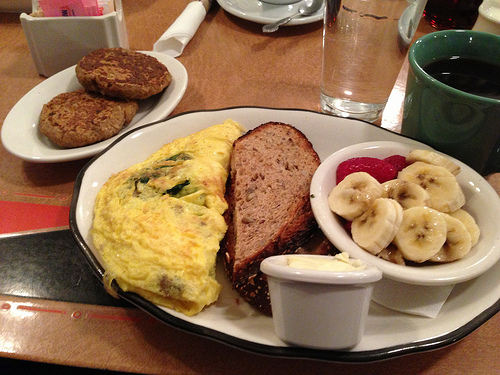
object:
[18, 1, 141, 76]
container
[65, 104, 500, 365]
plate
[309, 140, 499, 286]
bowl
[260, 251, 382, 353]
cup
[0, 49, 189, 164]
plate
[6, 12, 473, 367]
table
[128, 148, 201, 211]
filling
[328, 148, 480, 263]
bananas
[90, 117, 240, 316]
omelet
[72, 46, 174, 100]
sausage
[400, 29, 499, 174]
cup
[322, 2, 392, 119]
glass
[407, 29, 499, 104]
rim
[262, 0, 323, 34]
spoon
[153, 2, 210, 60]
napkin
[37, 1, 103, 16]
packets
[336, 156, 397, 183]
strawberries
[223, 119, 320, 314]
toast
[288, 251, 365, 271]
butter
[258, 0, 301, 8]
bowl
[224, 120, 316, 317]
bread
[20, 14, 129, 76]
holder